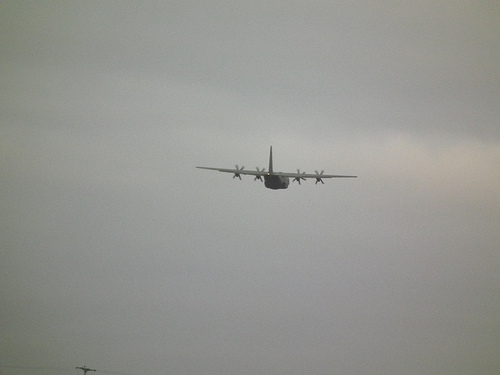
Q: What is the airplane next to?
A: A white cloud.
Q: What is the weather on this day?
A: Cloudy.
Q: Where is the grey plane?
A: In the sky.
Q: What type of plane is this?
A: C130.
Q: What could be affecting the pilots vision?
A: The clouds.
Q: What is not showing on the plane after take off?
A: The landing gear.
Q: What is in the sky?
A: Airplane.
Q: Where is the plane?
A: In the sky.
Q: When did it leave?
A: On a cloudy day.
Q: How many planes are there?
A: One.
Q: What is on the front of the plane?
A: Propellors.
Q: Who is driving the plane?
A: The pilot.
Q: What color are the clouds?
A: Grey.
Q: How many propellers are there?
A: Four.